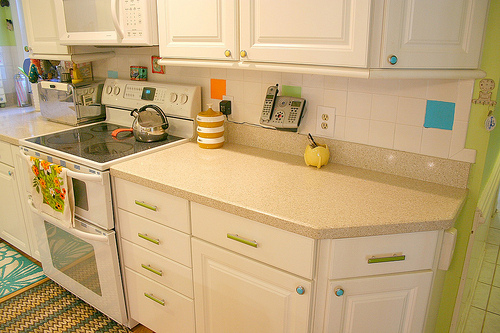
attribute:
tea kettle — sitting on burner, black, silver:
[130, 102, 170, 144]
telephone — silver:
[260, 80, 306, 131]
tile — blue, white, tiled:
[90, 49, 479, 164]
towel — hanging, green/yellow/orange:
[26, 153, 77, 229]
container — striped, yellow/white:
[195, 102, 226, 150]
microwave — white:
[56, 1, 160, 50]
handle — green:
[226, 231, 259, 247]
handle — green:
[137, 232, 161, 244]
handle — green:
[140, 260, 164, 277]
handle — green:
[143, 290, 169, 308]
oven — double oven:
[19, 145, 141, 328]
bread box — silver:
[36, 78, 105, 127]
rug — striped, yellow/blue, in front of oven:
[2, 277, 133, 331]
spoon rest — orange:
[110, 126, 134, 139]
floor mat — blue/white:
[0, 240, 47, 300]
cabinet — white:
[112, 172, 446, 332]